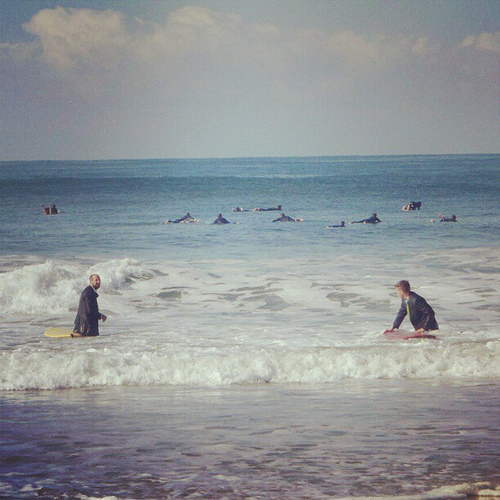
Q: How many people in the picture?
A: 12.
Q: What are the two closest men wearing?
A: Suits.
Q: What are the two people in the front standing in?
A: Water.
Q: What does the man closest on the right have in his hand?
A: Surfboard.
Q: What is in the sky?
A: Clouds.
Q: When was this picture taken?
A: Daytime.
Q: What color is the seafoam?
A: White.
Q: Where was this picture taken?
A: At the beach.